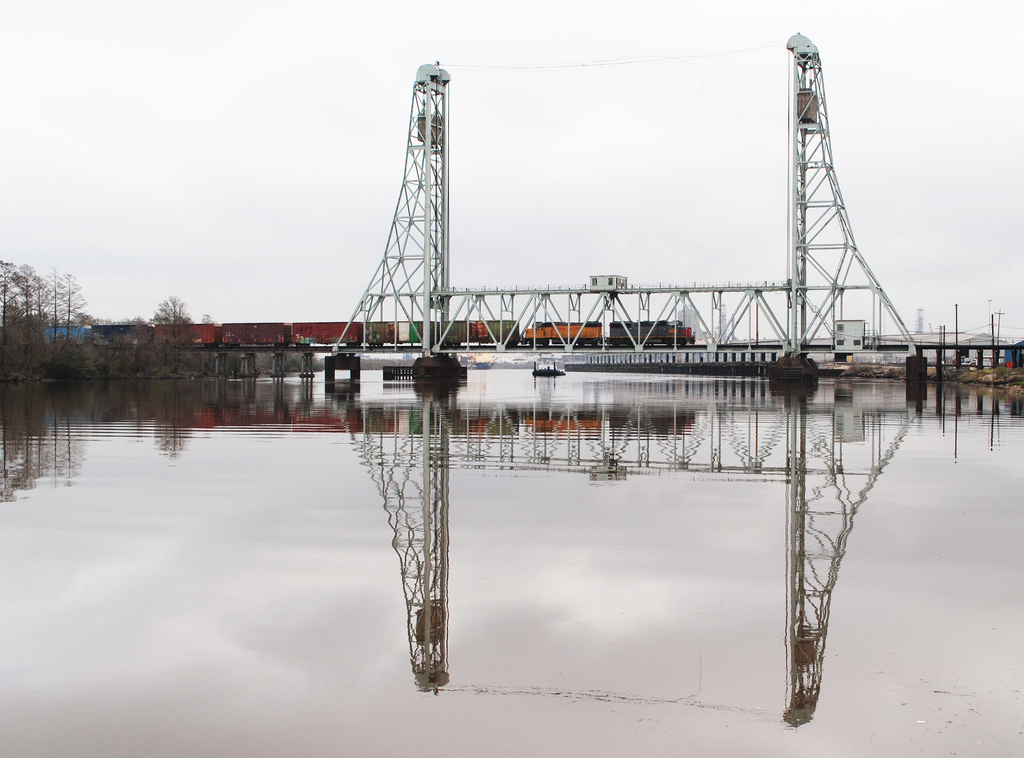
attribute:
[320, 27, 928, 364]
railings — bridge, reflection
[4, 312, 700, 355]
train — blue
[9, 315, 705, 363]
train — colorful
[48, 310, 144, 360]
cargo trailer — blue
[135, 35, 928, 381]
bridge — white